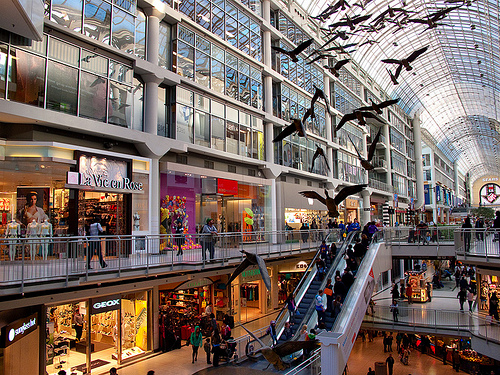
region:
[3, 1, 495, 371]
interior view of a large mall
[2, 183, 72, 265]
headless mannequins on display in a shop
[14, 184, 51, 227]
large image of a scantily clad woman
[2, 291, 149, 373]
illuminated signs outside of a store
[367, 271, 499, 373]
railing around elevated walkway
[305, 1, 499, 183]
the ceiling is curved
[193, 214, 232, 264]
woman leaning casually over railing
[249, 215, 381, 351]
people riding up and down escalators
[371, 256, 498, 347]
people walking about on elevated walkway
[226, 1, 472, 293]
bird figures suspended from above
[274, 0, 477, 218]
Flock of birds mobile hanging in a mall.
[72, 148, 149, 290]
A sign called a Vic en Rose.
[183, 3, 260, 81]
Blue skies shines through atrium.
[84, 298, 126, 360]
GEOX store is located on the first floor.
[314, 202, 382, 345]
People on a moving escalator.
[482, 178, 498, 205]
Arrow sign pointing downwards.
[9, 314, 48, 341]
"Snapshot" sign on the left hand side.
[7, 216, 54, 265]
Three mannequins on the upper floor.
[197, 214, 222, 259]
Man looking up at the top of the mall's ceiling.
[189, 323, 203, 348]
Customer wearing a green hoodie.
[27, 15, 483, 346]
Picture is taken in the shopping mall.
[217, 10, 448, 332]
Birds are flying inside the shopping mall.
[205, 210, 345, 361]
Birds are brown color.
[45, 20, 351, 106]
reflection is seen in mirror.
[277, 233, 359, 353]
escalators are grey color.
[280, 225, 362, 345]
people are standing in escalators.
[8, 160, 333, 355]
Lights are on.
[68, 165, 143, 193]
Letters are grey color.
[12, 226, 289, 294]
Rail is silver color.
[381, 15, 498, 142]
Roof is grey color.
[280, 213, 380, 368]
People riding an escalator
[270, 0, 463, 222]
Bird models suspended in shopping mall.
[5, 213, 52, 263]
Three mannequins in store window.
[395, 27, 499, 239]
Glass dome shopping mall.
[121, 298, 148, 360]
Display window in shopping mall.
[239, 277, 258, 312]
Display clothes on rack in shopping mall.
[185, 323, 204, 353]
Person wearing a green hoodie.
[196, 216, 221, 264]
Lady standing behind a rail.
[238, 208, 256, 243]
Orange and green display in store window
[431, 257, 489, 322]
Shopper walking in the mall.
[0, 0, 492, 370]
Large multi story indoor shopping mall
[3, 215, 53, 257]
Three manikins in lingerie without heads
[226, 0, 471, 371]
Flock of Canadian geese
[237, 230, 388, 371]
Shoppers going up and down on an escalator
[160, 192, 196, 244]
Colorful store front display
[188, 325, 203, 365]
Woman in skinny black pants and a green hoodie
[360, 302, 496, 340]
Safety railings along the mall walkways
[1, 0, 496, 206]
Large cylindrical glass ceiling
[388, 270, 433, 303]
People at a concession stand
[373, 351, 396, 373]
Man standing next to a brown trashcan